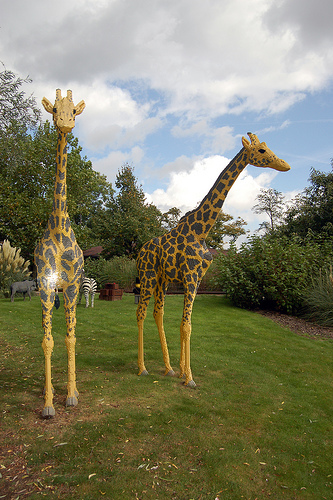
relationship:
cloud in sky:
[179, 98, 208, 126] [0, 2, 332, 252]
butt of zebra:
[82, 278, 99, 293] [82, 275, 102, 313]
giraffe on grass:
[128, 129, 296, 393] [6, 291, 329, 492]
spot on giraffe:
[183, 243, 197, 259] [128, 129, 296, 393]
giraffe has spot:
[128, 129, 296, 393] [165, 244, 179, 257]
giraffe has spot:
[31, 86, 91, 423] [60, 233, 76, 249]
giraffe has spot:
[31, 86, 91, 423] [55, 168, 68, 183]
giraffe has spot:
[128, 129, 296, 393] [183, 243, 197, 259]